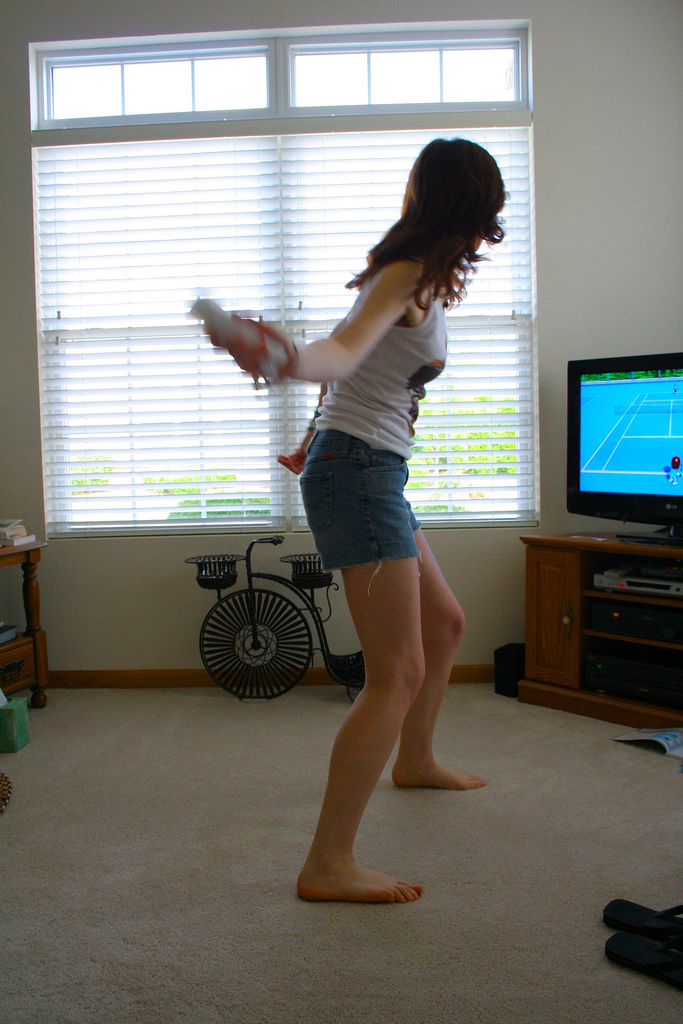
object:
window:
[294, 52, 368, 107]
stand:
[185, 534, 366, 703]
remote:
[189, 298, 289, 377]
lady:
[186, 139, 511, 903]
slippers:
[603, 896, 683, 991]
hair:
[344, 139, 510, 312]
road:
[322, 814, 683, 1022]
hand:
[211, 314, 297, 382]